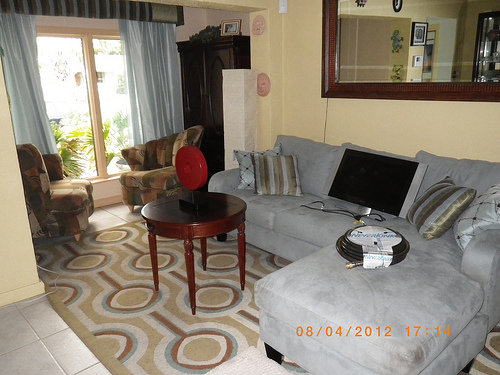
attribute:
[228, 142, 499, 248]
pillows — grey, brown, gold silver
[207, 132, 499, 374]
sectional — tan, gray, light grey, grey, fabric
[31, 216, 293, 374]
area rug — white blue, designed, beige, brown, tan blue brown, large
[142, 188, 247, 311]
table — round, small, wooden, wood, dark, brown, cherrywood color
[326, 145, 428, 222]
television — flat screen, flatscreen, small, silver, black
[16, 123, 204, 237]
armchairs — multi-color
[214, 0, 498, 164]
walls — light pastel yellow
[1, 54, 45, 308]
walls — light pastel yellow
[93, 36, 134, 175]
window — sunny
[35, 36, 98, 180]
window — sunny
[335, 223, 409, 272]
cable — rolled, new, brand new, black, coiled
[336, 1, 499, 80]
mirror — large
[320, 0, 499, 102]
frame — cherrywood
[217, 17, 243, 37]
framed picture — small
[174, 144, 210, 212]
statue — red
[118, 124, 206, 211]
chair — brown, plush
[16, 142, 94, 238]
chair — brown, plush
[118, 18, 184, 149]
curtain — blue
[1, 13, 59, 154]
curtain — blue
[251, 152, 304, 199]
pillow — small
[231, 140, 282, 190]
pillow — small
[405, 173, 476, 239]
pillow — small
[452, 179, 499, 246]
pillow — small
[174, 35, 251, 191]
cabinet — wooden